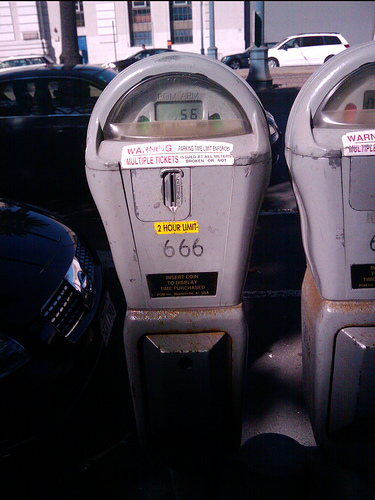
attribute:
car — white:
[268, 32, 352, 70]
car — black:
[109, 45, 170, 73]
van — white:
[268, 31, 351, 69]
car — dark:
[0, 199, 114, 423]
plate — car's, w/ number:
[92, 288, 120, 353]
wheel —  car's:
[267, 59, 280, 68]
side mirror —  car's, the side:
[281, 45, 289, 51]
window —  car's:
[278, 40, 298, 49]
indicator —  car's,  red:
[343, 44, 353, 50]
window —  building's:
[173, 0, 190, 43]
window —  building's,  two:
[130, 0, 151, 45]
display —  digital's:
[153, 102, 200, 121]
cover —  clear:
[103, 71, 251, 139]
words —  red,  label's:
[121, 139, 180, 168]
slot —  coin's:
[162, 167, 185, 210]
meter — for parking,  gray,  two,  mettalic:
[81, 51, 275, 491]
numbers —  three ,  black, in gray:
[162, 237, 205, 260]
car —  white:
[265, 34, 349, 65]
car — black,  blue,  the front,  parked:
[0, 199, 119, 407]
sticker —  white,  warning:
[122, 143, 176, 155]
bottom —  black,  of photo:
[1, 483, 374, 495]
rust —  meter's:
[302, 273, 322, 322]